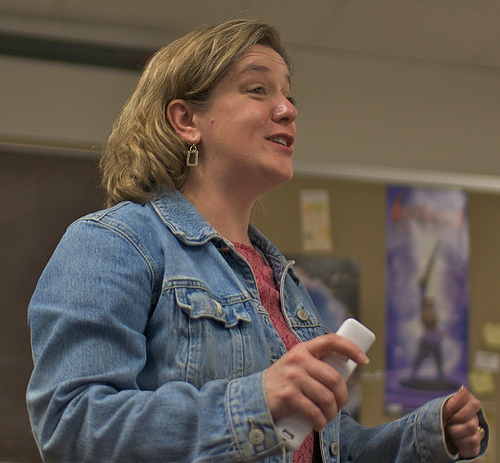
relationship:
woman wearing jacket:
[43, 21, 476, 461] [49, 170, 274, 437]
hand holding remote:
[263, 339, 343, 422] [321, 325, 380, 371]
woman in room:
[43, 21, 476, 461] [327, 52, 499, 317]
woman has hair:
[43, 21, 476, 461] [80, 115, 151, 168]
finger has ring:
[446, 386, 485, 428] [467, 418, 492, 441]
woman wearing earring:
[43, 21, 476, 461] [186, 144, 201, 168]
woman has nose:
[43, 21, 476, 461] [263, 96, 301, 128]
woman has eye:
[43, 21, 476, 461] [243, 74, 271, 106]